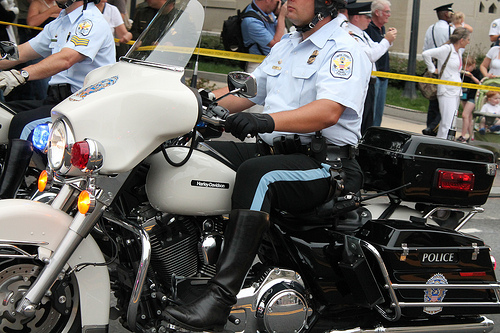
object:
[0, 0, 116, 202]
man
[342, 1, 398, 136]
man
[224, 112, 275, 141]
glove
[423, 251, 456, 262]
word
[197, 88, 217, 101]
gloves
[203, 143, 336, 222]
pants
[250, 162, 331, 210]
stripe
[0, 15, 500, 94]
caution tape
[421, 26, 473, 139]
woman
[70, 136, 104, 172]
light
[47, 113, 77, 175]
light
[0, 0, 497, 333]
bike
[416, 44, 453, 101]
purse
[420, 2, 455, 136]
police officer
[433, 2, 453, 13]
cap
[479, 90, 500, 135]
kid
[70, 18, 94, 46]
patch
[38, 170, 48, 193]
light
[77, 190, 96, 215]
light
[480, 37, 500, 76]
woman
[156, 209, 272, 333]
boot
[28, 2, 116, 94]
shirt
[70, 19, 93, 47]
emblem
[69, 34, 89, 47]
rank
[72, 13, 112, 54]
mans sholuder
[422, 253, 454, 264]
police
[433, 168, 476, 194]
light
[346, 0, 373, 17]
hat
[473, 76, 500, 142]
stroller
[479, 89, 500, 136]
toddler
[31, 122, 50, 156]
light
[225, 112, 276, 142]
hand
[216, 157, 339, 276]
leg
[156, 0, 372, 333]
man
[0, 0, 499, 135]
background